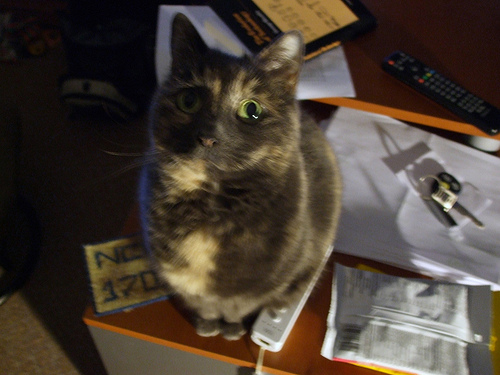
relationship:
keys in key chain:
[427, 170, 482, 227] [417, 174, 442, 201]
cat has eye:
[128, 10, 353, 350] [239, 97, 261, 121]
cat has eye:
[128, 10, 353, 350] [174, 88, 206, 117]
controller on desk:
[249, 240, 333, 352] [93, 22, 498, 369]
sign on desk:
[83, 235, 177, 312] [93, 22, 498, 369]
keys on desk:
[429, 171, 485, 229] [350, 116, 484, 356]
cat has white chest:
[145, 30, 340, 341] [161, 229, 224, 304]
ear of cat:
[253, 31, 304, 89] [145, 30, 340, 341]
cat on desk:
[145, 30, 340, 341] [173, 56, 488, 304]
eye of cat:
[237, 93, 262, 121] [128, 10, 353, 350]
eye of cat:
[177, 85, 202, 113] [128, 10, 353, 350]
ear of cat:
[253, 28, 304, 88] [128, 10, 353, 350]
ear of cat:
[170, 10, 205, 63] [128, 10, 353, 350]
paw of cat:
[220, 321, 250, 346] [128, 10, 353, 350]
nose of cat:
[192, 127, 222, 149] [128, 10, 353, 350]